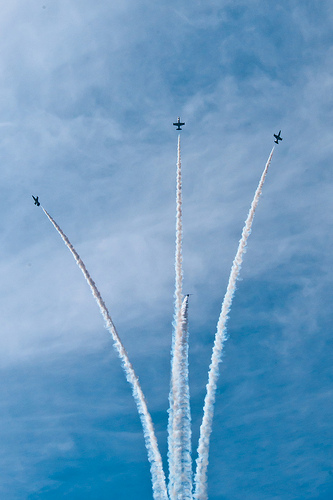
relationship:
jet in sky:
[272, 130, 283, 145] [0, 0, 333, 499]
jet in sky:
[171, 116, 186, 130] [0, 0, 333, 499]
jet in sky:
[182, 292, 194, 299] [0, 0, 333, 499]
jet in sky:
[31, 190, 41, 211] [0, 0, 333, 499]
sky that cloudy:
[0, 0, 333, 499] [1, 1, 332, 359]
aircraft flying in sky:
[272, 130, 283, 145] [0, 0, 333, 499]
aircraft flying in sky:
[171, 116, 186, 130] [0, 0, 333, 499]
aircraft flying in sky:
[31, 190, 41, 211] [0, 0, 333, 499]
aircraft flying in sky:
[182, 292, 194, 299] [0, 0, 333, 499]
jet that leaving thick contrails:
[171, 116, 186, 130] [168, 131, 182, 499]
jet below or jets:
[182, 292, 194, 299] [31, 116, 284, 206]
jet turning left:
[32, 193, 41, 207] [31, 193, 168, 490]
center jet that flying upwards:
[171, 116, 186, 130] [168, 113, 188, 499]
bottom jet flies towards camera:
[181, 290, 191, 299] [174, 288, 194, 499]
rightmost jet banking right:
[272, 130, 283, 145] [194, 127, 286, 500]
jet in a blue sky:
[171, 116, 186, 130] [0, 0, 333, 499]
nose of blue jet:
[276, 127, 284, 134] [272, 130, 283, 145]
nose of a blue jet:
[276, 127, 284, 134] [272, 130, 283, 145]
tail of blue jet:
[272, 139, 280, 144] [272, 130, 283, 145]